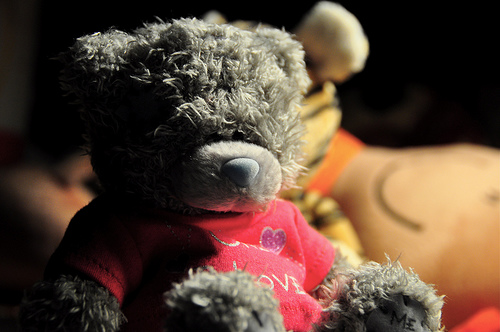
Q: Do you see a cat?
A: No, there are no cats.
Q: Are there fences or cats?
A: No, there are no cats or fences.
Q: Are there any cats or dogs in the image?
A: No, there are no dogs or cats.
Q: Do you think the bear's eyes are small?
A: Yes, the eyes are small.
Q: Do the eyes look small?
A: Yes, the eyes are small.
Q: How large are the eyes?
A: The eyes are small.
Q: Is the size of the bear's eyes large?
A: No, the eyes are small.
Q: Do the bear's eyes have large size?
A: No, the eyes are small.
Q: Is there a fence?
A: No, there are no fences.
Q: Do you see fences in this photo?
A: No, there are no fences.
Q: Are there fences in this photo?
A: No, there are no fences.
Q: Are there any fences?
A: No, there are no fences.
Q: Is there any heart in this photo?
A: Yes, there is a heart.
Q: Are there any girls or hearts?
A: Yes, there is a heart.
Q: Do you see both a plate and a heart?
A: No, there is a heart but no plates.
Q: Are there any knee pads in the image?
A: No, there are no knee pads.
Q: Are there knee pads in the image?
A: No, there are no knee pads.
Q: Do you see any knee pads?
A: No, there are no knee pads.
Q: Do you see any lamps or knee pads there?
A: No, there are no knee pads or lamps.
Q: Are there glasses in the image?
A: No, there are no glasses.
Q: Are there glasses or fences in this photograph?
A: No, there are no glasses or fences.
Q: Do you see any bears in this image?
A: Yes, there is a bear.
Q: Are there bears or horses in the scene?
A: Yes, there is a bear.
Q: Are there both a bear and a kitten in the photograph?
A: No, there is a bear but no kittens.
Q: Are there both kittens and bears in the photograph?
A: No, there is a bear but no kittens.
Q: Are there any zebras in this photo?
A: No, there are no zebras.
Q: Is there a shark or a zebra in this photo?
A: No, there are no zebras or sharks.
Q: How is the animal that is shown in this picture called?
A: The animal is a bear.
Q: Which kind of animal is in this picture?
A: The animal is a bear.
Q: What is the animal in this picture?
A: The animal is a bear.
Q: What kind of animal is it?
A: The animal is a bear.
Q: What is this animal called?
A: This is a bear.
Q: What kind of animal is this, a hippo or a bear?
A: This is a bear.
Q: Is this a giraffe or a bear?
A: This is a bear.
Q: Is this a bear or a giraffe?
A: This is a bear.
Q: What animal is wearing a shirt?
A: The bear is wearing a shirt.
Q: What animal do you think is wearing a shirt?
A: The animal is a bear.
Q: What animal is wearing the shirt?
A: The animal is a bear.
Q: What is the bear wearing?
A: The bear is wearing a shirt.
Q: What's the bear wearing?
A: The bear is wearing a shirt.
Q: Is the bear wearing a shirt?
A: Yes, the bear is wearing a shirt.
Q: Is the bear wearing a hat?
A: No, the bear is wearing a shirt.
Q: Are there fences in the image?
A: No, there are no fences.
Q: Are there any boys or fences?
A: No, there are no fences or boys.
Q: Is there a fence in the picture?
A: No, there are no fences.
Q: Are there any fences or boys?
A: No, there are no fences or boys.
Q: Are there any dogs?
A: No, there are no dogs.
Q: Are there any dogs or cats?
A: No, there are no dogs or cats.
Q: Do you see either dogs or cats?
A: No, there are no dogs or cats.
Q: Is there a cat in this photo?
A: No, there are no cats.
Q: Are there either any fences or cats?
A: No, there are no cats or fences.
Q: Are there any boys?
A: No, there are no boys.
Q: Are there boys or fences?
A: No, there are no boys or fences.